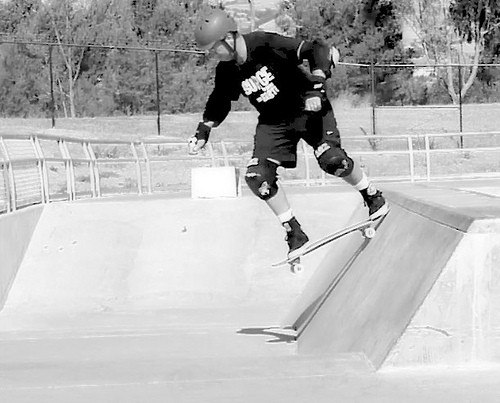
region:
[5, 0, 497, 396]
the picture is in black and white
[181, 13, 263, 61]
the man is wearing a helmet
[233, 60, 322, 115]
white lettering on shirt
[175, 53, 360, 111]
the shirt is black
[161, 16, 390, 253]
the man is wearing protective gear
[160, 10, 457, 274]
the man is going down ramp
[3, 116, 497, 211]
metal fence around skate ramps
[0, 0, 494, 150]
trees are behind the skate park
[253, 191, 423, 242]
skater's shoes are black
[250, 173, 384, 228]
skater's socks are white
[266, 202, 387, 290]
Skateboard under feet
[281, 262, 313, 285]
Wheel on a skateboard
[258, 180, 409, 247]
Black shoes on a skateboard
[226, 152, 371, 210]
Black knee pads on a man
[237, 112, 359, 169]
Black shorts on a skateboarder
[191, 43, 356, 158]
Black shirt on a man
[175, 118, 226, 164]
Glove on a hand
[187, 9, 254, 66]
Helmet on a head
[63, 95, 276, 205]
Fence by a skate park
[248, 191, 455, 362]
Ramp in a skate park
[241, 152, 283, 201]
a black knee pad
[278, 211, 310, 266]
a black and white shoe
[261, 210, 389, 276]
a skateboard on the ramp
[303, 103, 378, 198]
the leg of a man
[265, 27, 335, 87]
the arm of a man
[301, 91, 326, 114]
the hand of a man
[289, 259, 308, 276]
the wheel of a skateboard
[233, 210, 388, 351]
a shadow on the ground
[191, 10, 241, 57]
a helmet on the man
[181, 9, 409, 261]
a man on a skateboard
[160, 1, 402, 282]
skateboarder on a ramp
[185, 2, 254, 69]
helmet on skateboarder's head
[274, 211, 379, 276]
skateboard on a ramp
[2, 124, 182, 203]
fence surrounding skateboard park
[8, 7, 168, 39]
lush trees in the distance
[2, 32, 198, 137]
chain link fence by grass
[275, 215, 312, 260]
right sneaker on skateboarder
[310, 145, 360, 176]
knee pad on a skateboarder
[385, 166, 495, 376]
concrete ramp at a skate park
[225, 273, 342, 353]
shadow on ground of ramp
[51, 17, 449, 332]
A black and white photo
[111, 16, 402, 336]
Man on a skateboard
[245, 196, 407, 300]
feet on a skate board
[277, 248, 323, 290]
The wheels on a skateboard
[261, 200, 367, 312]
the front of a skateboard in the air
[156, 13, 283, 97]
A man wearing a helmet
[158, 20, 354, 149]
A man wearing elbow pads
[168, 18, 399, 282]
A man wearing knee pads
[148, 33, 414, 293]
A man wearing sneakers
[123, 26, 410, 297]
A skateboarder on a ramp